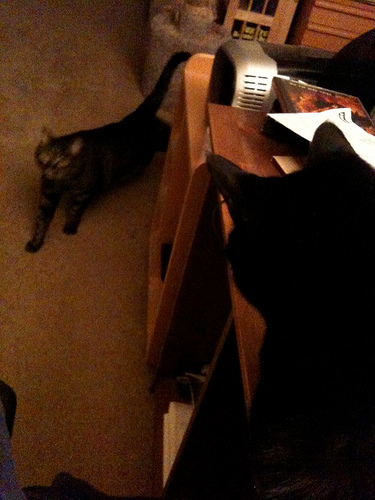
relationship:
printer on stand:
[209, 37, 340, 106] [144, 50, 226, 363]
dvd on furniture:
[274, 70, 375, 136] [143, 105, 267, 494]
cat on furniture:
[187, 136, 374, 499] [143, 105, 267, 494]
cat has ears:
[187, 136, 374, 499] [200, 153, 268, 213]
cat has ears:
[187, 136, 374, 499] [303, 120, 357, 160]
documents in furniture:
[156, 397, 189, 484] [143, 105, 267, 494]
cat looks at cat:
[187, 136, 374, 499] [23, 53, 202, 251]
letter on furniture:
[267, 106, 369, 165] [143, 105, 267, 494]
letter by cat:
[267, 106, 369, 165] [187, 136, 374, 499]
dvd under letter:
[274, 70, 375, 136] [267, 106, 369, 165]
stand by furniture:
[144, 50, 226, 363] [143, 105, 267, 494]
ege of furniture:
[205, 101, 260, 139] [143, 105, 267, 494]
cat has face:
[23, 53, 202, 251] [31, 129, 83, 180]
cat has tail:
[23, 53, 202, 251] [136, 48, 191, 116]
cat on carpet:
[23, 53, 202, 251] [8, 49, 169, 494]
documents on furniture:
[156, 397, 189, 484] [143, 105, 267, 494]